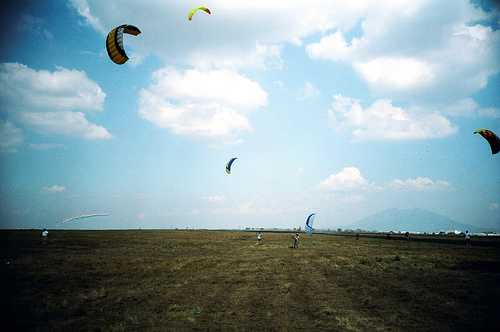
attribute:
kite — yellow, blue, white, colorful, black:
[105, 23, 141, 63]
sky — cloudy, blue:
[0, 0, 497, 232]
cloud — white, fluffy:
[137, 65, 269, 145]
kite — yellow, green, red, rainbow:
[187, 5, 213, 21]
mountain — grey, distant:
[344, 206, 469, 231]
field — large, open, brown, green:
[2, 228, 497, 331]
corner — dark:
[0, 1, 29, 38]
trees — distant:
[244, 228, 339, 234]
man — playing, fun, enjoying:
[41, 227, 50, 245]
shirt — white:
[41, 230, 49, 236]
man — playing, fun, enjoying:
[291, 232, 302, 249]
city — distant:
[390, 228, 497, 236]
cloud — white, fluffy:
[11, 107, 115, 140]